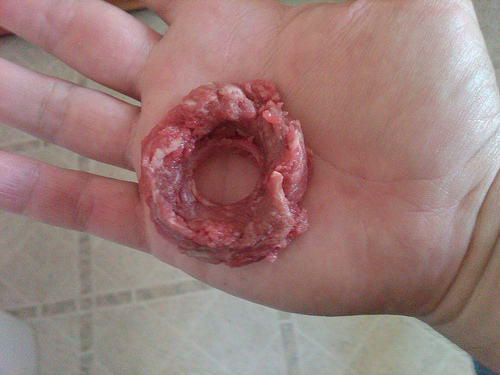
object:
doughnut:
[137, 80, 315, 269]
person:
[0, 0, 499, 374]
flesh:
[342, 133, 456, 262]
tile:
[88, 288, 290, 374]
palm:
[129, 10, 499, 314]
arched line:
[309, 149, 439, 186]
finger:
[0, 58, 138, 175]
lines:
[50, 84, 82, 146]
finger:
[0, 148, 144, 254]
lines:
[17, 159, 44, 216]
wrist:
[435, 171, 499, 373]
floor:
[0, 0, 499, 375]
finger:
[0, 1, 164, 101]